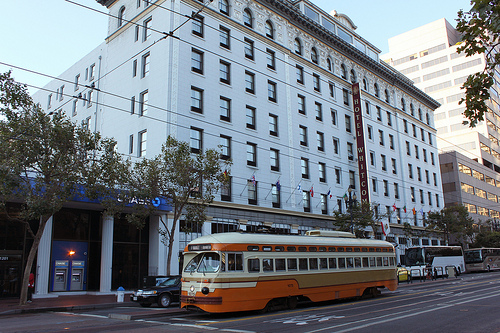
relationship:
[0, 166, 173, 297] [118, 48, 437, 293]
bank next to hotel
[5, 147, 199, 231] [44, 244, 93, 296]
blue overhang over atm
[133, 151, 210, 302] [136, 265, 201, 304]
tree behind car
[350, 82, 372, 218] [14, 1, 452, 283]
sign on building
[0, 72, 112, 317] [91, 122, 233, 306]
tree to left of tree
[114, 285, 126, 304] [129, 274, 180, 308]
fire hydrant near car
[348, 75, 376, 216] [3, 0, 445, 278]
sign on hotel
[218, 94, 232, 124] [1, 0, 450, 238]
window on building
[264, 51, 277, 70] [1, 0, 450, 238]
window on building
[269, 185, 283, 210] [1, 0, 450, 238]
window on building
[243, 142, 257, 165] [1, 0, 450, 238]
window on building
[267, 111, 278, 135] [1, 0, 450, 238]
window on building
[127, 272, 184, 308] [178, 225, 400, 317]
car behind trolley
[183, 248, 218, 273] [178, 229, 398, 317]
window on orange trolley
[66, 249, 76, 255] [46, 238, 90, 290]
light above atm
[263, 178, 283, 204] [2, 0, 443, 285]
flagpoles attached to white building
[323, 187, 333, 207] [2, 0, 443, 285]
flagpoles attached to white building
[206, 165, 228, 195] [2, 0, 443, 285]
flagpoles attached to white building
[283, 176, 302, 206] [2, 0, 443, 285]
flagpoles attached to white building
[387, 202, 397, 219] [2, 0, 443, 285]
flagpoles attached to white building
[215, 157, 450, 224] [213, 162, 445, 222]
flags on poles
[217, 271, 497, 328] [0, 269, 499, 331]
lines on street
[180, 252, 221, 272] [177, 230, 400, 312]
windshield on bus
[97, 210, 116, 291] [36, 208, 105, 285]
column on building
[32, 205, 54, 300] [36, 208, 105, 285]
column on building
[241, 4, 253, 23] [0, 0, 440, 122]
window on top floor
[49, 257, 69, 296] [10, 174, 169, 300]
atm machine in front of chase bank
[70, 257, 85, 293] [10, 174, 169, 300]
atm machine in front of chase bank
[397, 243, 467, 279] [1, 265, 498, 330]
tour bus parked on side of road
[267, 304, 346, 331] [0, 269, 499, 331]
instructions painted on street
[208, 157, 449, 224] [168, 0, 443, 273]
flags on building front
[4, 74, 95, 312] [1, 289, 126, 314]
tree on sidewalk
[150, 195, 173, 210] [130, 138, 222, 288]
sign hidden by tree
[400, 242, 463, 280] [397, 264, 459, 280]
rails on median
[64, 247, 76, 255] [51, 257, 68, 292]
light above atm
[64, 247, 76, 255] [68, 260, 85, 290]
light above atm